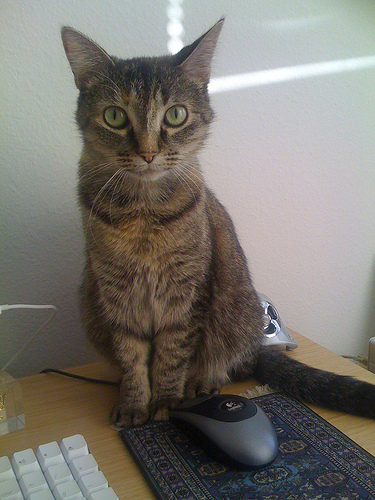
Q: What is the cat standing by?
A: A mouse.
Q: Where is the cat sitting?
A: On a desk.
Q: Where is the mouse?
A: On the mousepad.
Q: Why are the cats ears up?
A: He's alert.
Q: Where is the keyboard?
A: To the left of the mouse.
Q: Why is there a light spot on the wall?
A: Glare from the light.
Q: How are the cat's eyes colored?
A: Intense green.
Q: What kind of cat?
A: Brown.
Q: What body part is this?
A: Legs.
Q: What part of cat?
A: Whiskers.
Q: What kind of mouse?
A: Computer.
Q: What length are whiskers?
A: Long.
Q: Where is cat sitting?
A: Desk.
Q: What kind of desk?
A: Wood.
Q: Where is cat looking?
A: Camera.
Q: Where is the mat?
A: On the desk.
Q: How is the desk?
A: Made of wood.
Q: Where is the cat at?
A: Table.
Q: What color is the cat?
A: Brown.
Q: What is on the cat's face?
A: Whiskers.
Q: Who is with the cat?
A: No one.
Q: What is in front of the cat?
A: Mouse.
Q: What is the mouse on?
A: Mouse pad.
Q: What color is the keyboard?
A: White.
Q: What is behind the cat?
A: Wall.